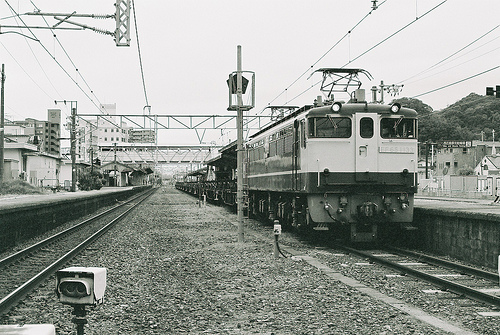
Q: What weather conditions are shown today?
A: It is overcast.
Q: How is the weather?
A: It is overcast.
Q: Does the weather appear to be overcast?
A: Yes, it is overcast.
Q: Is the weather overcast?
A: Yes, it is overcast.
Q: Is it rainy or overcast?
A: It is overcast.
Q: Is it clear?
A: No, it is overcast.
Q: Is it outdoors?
A: Yes, it is outdoors.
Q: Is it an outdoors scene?
A: Yes, it is outdoors.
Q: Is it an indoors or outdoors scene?
A: It is outdoors.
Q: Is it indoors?
A: No, it is outdoors.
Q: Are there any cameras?
A: Yes, there is a camera.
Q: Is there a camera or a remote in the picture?
A: Yes, there is a camera.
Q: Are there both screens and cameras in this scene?
A: No, there is a camera but no screens.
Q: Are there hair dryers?
A: No, there are no hair dryers.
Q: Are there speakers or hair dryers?
A: No, there are no hair dryers or speakers.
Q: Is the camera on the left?
A: Yes, the camera is on the left of the image.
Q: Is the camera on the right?
A: No, the camera is on the left of the image.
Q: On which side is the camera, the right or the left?
A: The camera is on the left of the image.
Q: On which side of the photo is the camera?
A: The camera is on the left of the image.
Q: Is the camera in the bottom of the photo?
A: Yes, the camera is in the bottom of the image.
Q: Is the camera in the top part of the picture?
A: No, the camera is in the bottom of the image.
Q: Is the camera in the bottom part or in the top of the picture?
A: The camera is in the bottom of the image.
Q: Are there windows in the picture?
A: Yes, there is a window.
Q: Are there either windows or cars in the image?
A: Yes, there is a window.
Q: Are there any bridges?
A: Yes, there is a bridge.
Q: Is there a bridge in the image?
A: Yes, there is a bridge.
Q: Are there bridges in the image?
A: Yes, there is a bridge.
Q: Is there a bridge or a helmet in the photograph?
A: Yes, there is a bridge.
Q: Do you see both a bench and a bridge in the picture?
A: No, there is a bridge but no benches.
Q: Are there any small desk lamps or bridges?
A: Yes, there is a small bridge.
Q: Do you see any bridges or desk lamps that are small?
A: Yes, the bridge is small.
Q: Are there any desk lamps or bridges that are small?
A: Yes, the bridge is small.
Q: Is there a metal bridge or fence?
A: Yes, there is a metal bridge.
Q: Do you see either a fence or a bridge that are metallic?
A: Yes, the bridge is metallic.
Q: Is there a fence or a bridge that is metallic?
A: Yes, the bridge is metallic.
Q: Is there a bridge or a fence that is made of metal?
A: Yes, the bridge is made of metal.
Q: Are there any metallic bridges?
A: Yes, there is a metal bridge.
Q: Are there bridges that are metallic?
A: Yes, there is a bridge that is metallic.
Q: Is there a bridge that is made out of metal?
A: Yes, there is a bridge that is made of metal.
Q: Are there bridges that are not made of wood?
A: Yes, there is a bridge that is made of metal.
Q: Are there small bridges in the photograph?
A: Yes, there is a small bridge.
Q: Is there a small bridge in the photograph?
A: Yes, there is a small bridge.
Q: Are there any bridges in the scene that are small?
A: Yes, there is a bridge that is small.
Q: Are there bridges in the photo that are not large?
A: Yes, there is a small bridge.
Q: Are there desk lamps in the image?
A: No, there are no desk lamps.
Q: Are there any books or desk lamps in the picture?
A: No, there are no desk lamps or books.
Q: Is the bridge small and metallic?
A: Yes, the bridge is small and metallic.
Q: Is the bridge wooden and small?
A: No, the bridge is small but metallic.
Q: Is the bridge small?
A: Yes, the bridge is small.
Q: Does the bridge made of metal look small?
A: Yes, the bridge is small.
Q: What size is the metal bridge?
A: The bridge is small.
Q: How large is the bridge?
A: The bridge is small.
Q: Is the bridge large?
A: No, the bridge is small.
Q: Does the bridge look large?
A: No, the bridge is small.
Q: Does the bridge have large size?
A: No, the bridge is small.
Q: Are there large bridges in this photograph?
A: No, there is a bridge but it is small.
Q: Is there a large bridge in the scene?
A: No, there is a bridge but it is small.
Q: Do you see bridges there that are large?
A: No, there is a bridge but it is small.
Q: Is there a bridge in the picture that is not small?
A: No, there is a bridge but it is small.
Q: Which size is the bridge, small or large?
A: The bridge is small.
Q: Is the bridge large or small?
A: The bridge is small.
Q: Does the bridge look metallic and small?
A: Yes, the bridge is metallic and small.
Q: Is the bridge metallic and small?
A: Yes, the bridge is metallic and small.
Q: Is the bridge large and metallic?
A: No, the bridge is metallic but small.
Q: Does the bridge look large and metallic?
A: No, the bridge is metallic but small.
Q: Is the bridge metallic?
A: Yes, the bridge is metallic.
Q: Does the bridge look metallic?
A: Yes, the bridge is metallic.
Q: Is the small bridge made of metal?
A: Yes, the bridge is made of metal.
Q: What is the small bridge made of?
A: The bridge is made of metal.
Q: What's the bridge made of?
A: The bridge is made of metal.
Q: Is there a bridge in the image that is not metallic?
A: No, there is a bridge but it is metallic.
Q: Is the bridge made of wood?
A: No, the bridge is made of metal.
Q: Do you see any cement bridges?
A: No, there is a bridge but it is made of metal.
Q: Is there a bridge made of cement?
A: No, there is a bridge but it is made of metal.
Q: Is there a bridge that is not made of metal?
A: No, there is a bridge but it is made of metal.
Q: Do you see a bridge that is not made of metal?
A: No, there is a bridge but it is made of metal.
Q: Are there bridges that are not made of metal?
A: No, there is a bridge but it is made of metal.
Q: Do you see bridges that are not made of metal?
A: No, there is a bridge but it is made of metal.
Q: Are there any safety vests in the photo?
A: No, there are no safety vests.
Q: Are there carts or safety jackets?
A: No, there are no safety jackets or carts.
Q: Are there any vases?
A: No, there are no vases.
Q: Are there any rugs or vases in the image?
A: No, there are no vases or rugs.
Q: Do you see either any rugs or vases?
A: No, there are no vases or rugs.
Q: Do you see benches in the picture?
A: No, there are no benches.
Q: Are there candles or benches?
A: No, there are no benches or candles.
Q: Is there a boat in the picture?
A: No, there are no boats.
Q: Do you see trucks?
A: No, there are no trucks.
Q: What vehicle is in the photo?
A: The vehicle is a locomotive.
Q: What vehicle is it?
A: The vehicle is a locomotive.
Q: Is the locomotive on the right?
A: Yes, the locomotive is on the right of the image.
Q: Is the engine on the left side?
A: No, the engine is on the right of the image.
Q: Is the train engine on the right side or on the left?
A: The train engine is on the right of the image.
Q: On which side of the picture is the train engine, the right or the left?
A: The train engine is on the right of the image.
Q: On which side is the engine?
A: The engine is on the right of the image.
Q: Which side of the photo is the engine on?
A: The engine is on the right of the image.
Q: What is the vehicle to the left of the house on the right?
A: The vehicle is a locomotive.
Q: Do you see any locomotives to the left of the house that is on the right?
A: Yes, there is a locomotive to the left of the house.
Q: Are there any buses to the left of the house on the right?
A: No, there is a locomotive to the left of the house.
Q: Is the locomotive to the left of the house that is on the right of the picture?
A: Yes, the locomotive is to the left of the house.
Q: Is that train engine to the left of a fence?
A: No, the train engine is to the left of the house.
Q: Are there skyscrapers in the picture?
A: Yes, there are skyscrapers.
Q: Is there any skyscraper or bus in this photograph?
A: Yes, there are skyscrapers.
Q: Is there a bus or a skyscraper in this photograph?
A: Yes, there are skyscrapers.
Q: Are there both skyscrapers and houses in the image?
A: Yes, there are both skyscrapers and a house.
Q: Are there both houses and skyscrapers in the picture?
A: Yes, there are both skyscrapers and a house.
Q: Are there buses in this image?
A: No, there are no buses.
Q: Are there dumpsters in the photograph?
A: No, there are no dumpsters.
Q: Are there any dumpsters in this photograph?
A: No, there are no dumpsters.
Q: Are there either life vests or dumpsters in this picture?
A: No, there are no dumpsters or life vests.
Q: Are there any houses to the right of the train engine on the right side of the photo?
A: Yes, there is a house to the right of the locomotive.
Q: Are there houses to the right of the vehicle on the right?
A: Yes, there is a house to the right of the locomotive.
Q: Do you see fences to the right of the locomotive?
A: No, there is a house to the right of the locomotive.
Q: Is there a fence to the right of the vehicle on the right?
A: No, there is a house to the right of the locomotive.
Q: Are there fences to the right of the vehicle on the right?
A: No, there is a house to the right of the locomotive.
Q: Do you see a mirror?
A: No, there are no mirrors.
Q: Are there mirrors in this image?
A: No, there are no mirrors.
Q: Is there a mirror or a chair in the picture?
A: No, there are no mirrors or chairs.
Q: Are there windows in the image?
A: Yes, there is a window.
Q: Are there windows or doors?
A: Yes, there is a window.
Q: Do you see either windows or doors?
A: Yes, there is a window.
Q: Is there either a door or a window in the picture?
A: Yes, there is a window.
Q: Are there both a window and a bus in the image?
A: No, there is a window but no buses.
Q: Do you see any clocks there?
A: No, there are no clocks.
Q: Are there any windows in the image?
A: Yes, there is a window.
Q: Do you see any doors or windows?
A: Yes, there is a window.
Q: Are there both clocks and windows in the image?
A: No, there is a window but no clocks.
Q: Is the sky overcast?
A: Yes, the sky is overcast.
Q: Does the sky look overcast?
A: Yes, the sky is overcast.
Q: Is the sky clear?
A: No, the sky is overcast.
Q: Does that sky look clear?
A: No, the sky is overcast.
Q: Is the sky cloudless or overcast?
A: The sky is overcast.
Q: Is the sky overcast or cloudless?
A: The sky is overcast.